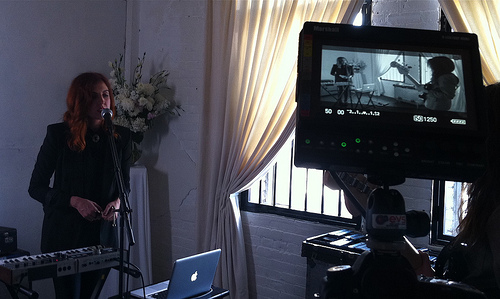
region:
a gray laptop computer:
[131, 245, 221, 295]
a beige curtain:
[192, 0, 354, 295]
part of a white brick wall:
[245, 207, 302, 293]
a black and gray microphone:
[100, 102, 110, 124]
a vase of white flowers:
[100, 55, 181, 165]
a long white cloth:
[110, 161, 155, 291]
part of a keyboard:
[0, 242, 131, 288]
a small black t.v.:
[295, 11, 480, 173]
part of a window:
[250, 145, 342, 219]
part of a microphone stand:
[105, 138, 136, 291]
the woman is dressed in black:
[17, 55, 154, 295]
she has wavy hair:
[13, 51, 153, 267]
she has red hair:
[22, 53, 160, 296]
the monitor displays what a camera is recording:
[282, 10, 494, 177]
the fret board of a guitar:
[387, 58, 432, 93]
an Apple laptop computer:
[124, 244, 244, 297]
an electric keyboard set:
[3, 236, 147, 278]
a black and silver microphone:
[96, 100, 128, 149]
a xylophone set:
[303, 218, 460, 273]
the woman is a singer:
[0, 55, 194, 296]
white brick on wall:
[136, 27, 201, 73]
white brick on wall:
[255, 250, 270, 265]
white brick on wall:
[186, 195, 191, 215]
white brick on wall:
[175, 145, 195, 180]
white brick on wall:
[170, 230, 195, 260]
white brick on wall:
[180, 107, 196, 137]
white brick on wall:
[271, 252, 291, 267]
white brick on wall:
[261, 232, 286, 252]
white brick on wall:
[407, 185, 418, 195]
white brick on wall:
[236, 211, 262, 233]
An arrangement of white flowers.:
[105, 48, 179, 165]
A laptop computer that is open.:
[138, 245, 223, 297]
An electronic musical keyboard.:
[1, 229, 130, 278]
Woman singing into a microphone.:
[24, 65, 158, 288]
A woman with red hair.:
[31, 58, 136, 170]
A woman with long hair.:
[42, 63, 132, 156]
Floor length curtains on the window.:
[206, 3, 494, 298]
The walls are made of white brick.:
[13, 8, 438, 297]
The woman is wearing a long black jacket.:
[21, 63, 141, 242]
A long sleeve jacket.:
[32, 111, 138, 248]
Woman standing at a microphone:
[27, 71, 138, 298]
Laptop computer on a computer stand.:
[130, 248, 228, 298]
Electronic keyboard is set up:
[0, 241, 140, 296]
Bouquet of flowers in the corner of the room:
[85, 52, 187, 173]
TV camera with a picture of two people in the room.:
[292, 19, 486, 296]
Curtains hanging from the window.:
[207, 0, 373, 297]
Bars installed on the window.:
[242, 128, 358, 220]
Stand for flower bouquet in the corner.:
[115, 165, 158, 296]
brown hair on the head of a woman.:
[62, 72, 117, 152]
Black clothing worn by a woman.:
[27, 119, 133, 297]